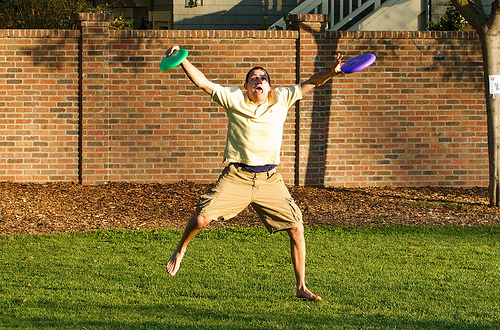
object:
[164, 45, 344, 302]
man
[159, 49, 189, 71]
discs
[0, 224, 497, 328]
grass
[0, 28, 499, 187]
wall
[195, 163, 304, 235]
shorts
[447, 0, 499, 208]
tree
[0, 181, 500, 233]
mulch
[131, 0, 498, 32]
house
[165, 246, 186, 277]
feet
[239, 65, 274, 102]
head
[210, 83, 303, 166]
shirt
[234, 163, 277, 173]
boxers